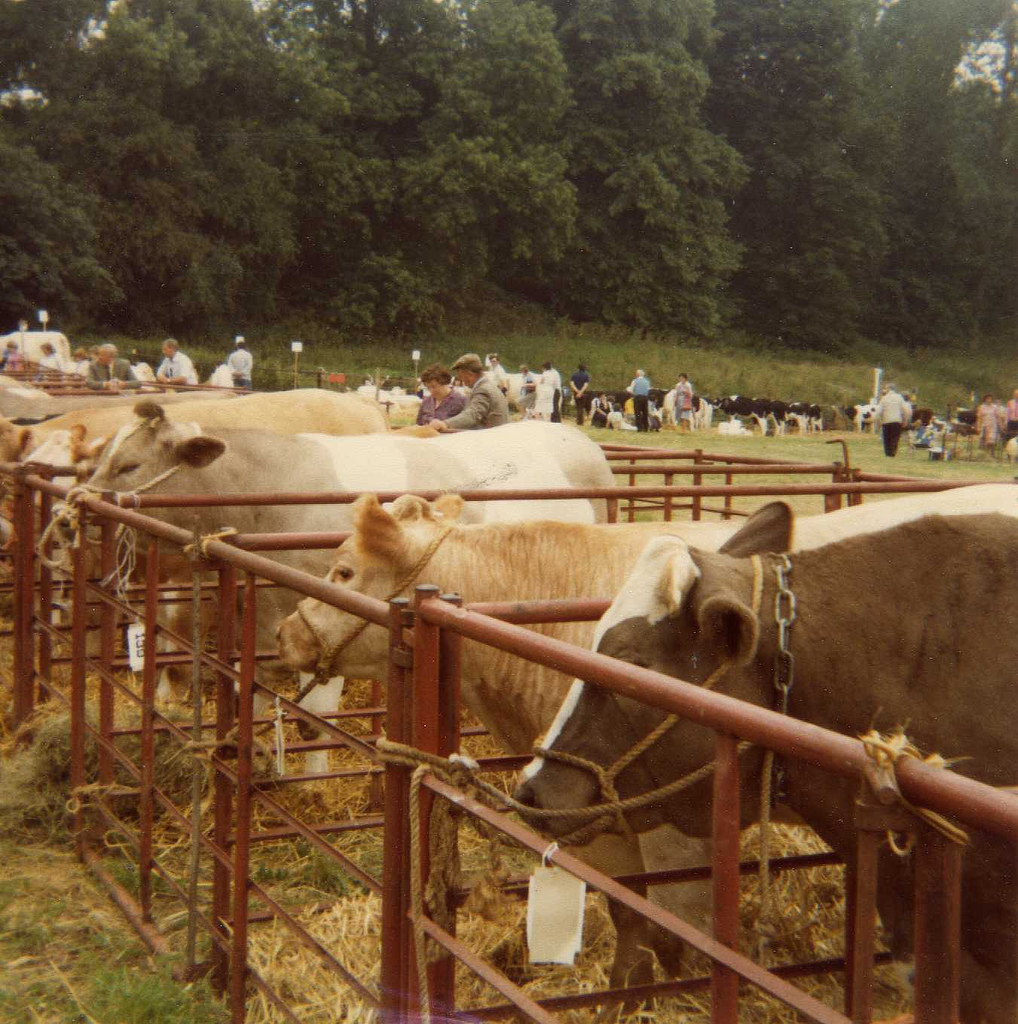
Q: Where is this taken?
A: At the feeding troughs of a farm.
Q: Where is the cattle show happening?
A: A farm.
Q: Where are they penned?
A: On a farm.